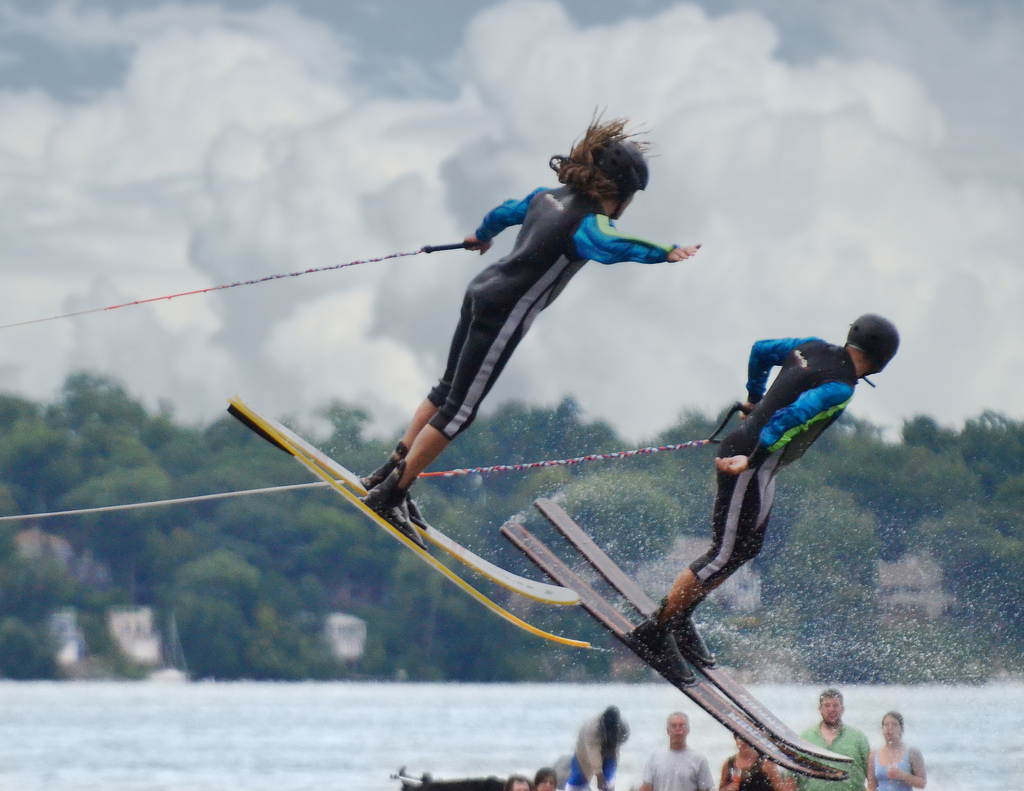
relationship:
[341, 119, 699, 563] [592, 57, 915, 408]
woman wearing helmets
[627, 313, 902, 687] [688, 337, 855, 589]
man wearing wet suits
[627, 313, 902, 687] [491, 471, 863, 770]
man on skiis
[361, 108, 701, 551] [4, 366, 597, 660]
people in skiis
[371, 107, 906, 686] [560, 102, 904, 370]
people wearing helmets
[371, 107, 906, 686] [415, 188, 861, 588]
people in wet suits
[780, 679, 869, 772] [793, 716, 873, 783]
man in shirt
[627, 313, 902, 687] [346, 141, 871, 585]
man in wet suit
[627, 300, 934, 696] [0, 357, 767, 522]
man holding rope